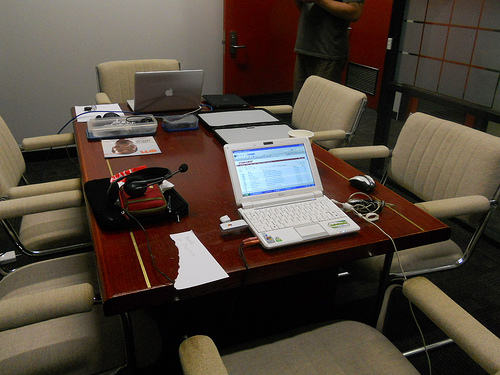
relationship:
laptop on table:
[218, 140, 361, 261] [189, 180, 228, 237]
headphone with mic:
[113, 160, 196, 207] [175, 160, 193, 179]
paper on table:
[162, 225, 236, 305] [189, 180, 228, 237]